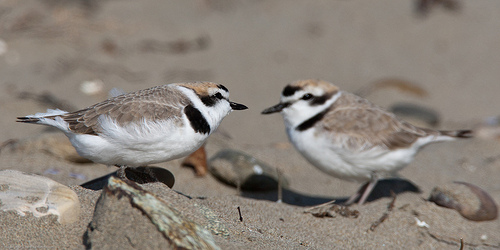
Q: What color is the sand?
A: Tan.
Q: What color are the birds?
A: Black, White and Tan.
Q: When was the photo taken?
A: Daytime.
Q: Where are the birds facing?
A: Each other.